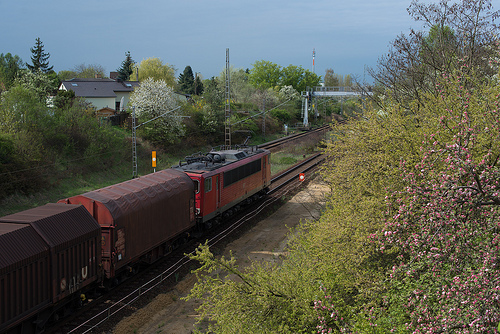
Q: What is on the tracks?
A: A train.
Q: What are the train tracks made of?
A: Metal.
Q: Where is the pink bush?
A: Bottom right.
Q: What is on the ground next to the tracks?
A: Dirt.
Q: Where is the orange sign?
A: To the left of the train.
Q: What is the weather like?
A: Clear and sunny.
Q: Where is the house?
A: Behind some trees on the left.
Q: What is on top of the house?
A: A roof.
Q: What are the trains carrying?
A: Cargo.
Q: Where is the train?
A: Tracks.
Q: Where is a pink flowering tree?
A: Right side of tracks.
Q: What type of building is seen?
A: White house with dark roof.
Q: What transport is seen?
A: Train.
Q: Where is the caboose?
A: On the train.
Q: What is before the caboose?
A: The last two cars.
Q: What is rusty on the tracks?
A: The train.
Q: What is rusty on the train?
A: The cars.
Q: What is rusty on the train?
A: The first two cars.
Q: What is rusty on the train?
A: The rails.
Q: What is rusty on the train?
A: The metal.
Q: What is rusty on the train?
A: The window bars.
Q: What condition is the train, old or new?
A: Old train.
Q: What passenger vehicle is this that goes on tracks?
A: Train.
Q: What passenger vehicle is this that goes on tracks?
A: Train.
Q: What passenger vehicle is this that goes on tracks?
A: Train.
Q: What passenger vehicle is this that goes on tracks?
A: Train.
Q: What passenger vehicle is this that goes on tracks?
A: Train.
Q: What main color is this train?
A: Red.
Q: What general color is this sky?
A: Blue.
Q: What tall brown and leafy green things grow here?
A: Trees.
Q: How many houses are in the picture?
A: One.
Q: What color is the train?
A: Red.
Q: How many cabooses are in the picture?
A: Three.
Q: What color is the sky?
A: Blue.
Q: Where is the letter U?
A: On the train.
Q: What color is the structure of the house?
A: White.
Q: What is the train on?
A: Train tracks.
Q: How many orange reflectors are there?
A: One.